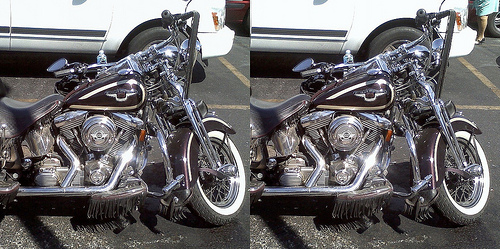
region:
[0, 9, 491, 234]
THE BIKE IS BLACK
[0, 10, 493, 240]
THE BIKE IS PARKED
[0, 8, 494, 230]
THE BIKE IS IN ON PAVEMENT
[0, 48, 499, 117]
THE LINES ARE PAINTED ON THE PAVEMENT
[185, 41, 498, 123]
THE LINE IS WORN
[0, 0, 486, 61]
THE VEHICLE IS WHITE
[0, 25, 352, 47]
THE VEHICLE HAS A BLACK STRIPE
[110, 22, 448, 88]
THE VEHICLE HAS A BLACK TIRE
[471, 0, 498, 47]
THE WOMAN IS IN FRONT OF THE WHITE VEHICLE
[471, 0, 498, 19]
THE WOMAN IS WEARING A BLUE SKIRT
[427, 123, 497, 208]
The tire is black.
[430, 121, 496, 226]
The tire is white washed.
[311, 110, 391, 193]
The engine is silver.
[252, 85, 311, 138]
The seat is black.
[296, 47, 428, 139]
The bike is black.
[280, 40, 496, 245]
THe bike is parked.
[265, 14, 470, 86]
The white car is white.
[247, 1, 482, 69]
The car is parked.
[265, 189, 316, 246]
The bike is casting a shadow.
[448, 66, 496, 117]
The ground is concrete.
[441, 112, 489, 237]
The tire is white wall.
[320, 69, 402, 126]
The bike is black.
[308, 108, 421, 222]
The engine is metal.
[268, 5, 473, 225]
The bike is parked.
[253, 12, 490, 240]
The sun is shining on the bike.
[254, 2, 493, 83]
The car is white.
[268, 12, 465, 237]
The car is next to the bike.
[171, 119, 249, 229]
white wall motorcycle tire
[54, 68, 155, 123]
gas tank on motorcycle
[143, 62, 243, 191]
front forks of motorcycle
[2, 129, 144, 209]
chrome motorcycle exhaust pipes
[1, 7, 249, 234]
older style red motorcycle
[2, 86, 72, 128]
black leather motorcycle seat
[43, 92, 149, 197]
chromed out motorcycle engine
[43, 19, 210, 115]
chrome handlebars of motorcycle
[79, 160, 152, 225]
chrome footboard of motorcycle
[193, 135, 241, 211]
chrome spokes on motorcycle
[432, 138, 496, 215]
front wheel on the motorcycle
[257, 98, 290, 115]
the seat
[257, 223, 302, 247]
shadow on the ground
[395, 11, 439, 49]
handle bars on the motorcycle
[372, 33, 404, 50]
wheel of the car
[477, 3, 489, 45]
a person leg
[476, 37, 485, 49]
a person wearing shoes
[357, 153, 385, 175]
reflection of light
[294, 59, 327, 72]
a mirror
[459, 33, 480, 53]
bumber on the white car